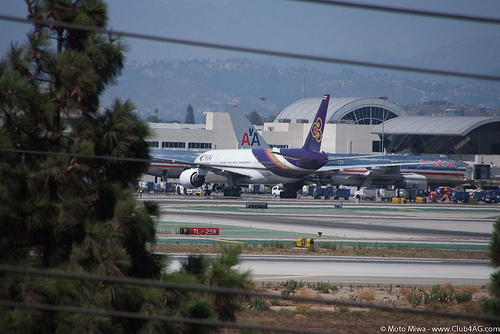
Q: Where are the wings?
A: On plane.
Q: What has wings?
A: The plane.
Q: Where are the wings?
A: On plane.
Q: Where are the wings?
A: On plane.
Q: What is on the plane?
A: Wings.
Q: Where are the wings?
A: On plane.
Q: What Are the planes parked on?
A: Tarmac.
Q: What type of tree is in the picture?
A: Pine tree.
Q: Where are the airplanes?
A: The airport.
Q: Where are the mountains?
A: Behind the airport.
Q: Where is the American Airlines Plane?
A: The airport.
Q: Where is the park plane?
A: The airport.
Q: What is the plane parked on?
A: Runway.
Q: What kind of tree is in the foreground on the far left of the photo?
A: Evergreen.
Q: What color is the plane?
A: Blue, white, and red.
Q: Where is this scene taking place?
A: Airport.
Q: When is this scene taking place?
A: Day time.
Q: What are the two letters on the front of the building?
A: AA.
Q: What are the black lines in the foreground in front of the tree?
A: Power lines.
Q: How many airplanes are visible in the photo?
A: One.